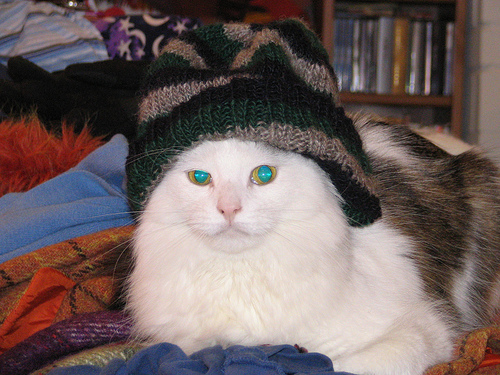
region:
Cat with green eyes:
[10, 3, 485, 360]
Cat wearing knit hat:
[117, 18, 492, 361]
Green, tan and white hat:
[117, 15, 382, 225]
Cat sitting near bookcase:
[100, 4, 481, 361]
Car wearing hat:
[124, 18, 462, 336]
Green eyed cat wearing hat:
[121, 19, 482, 349]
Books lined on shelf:
[321, 3, 486, 107]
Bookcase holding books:
[319, 3, 469, 103]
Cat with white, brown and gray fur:
[111, 39, 494, 336]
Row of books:
[322, 11, 461, 101]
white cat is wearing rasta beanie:
[109, 67, 475, 363]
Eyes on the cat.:
[160, 125, 379, 222]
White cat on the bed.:
[111, 112, 431, 364]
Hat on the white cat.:
[112, 28, 374, 217]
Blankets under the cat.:
[50, 95, 258, 350]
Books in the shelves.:
[324, 8, 469, 117]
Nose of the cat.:
[172, 181, 299, 268]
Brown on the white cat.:
[360, 137, 495, 297]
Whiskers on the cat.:
[132, 200, 460, 302]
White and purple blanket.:
[79, 16, 209, 76]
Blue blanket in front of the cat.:
[75, 337, 301, 372]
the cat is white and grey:
[172, 153, 491, 367]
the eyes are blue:
[173, 158, 305, 210]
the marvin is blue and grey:
[150, 21, 379, 188]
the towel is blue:
[11, 174, 124, 251]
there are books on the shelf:
[330, 12, 462, 96]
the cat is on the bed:
[143, 72, 495, 314]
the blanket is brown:
[6, 246, 118, 310]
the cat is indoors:
[3, 18, 498, 368]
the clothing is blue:
[102, 348, 282, 374]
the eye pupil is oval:
[162, 138, 338, 260]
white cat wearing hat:
[104, 14, 486, 369]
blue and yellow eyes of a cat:
[169, 161, 299, 194]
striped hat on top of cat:
[116, 11, 369, 166]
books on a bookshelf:
[339, 8, 458, 107]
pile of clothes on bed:
[0, 156, 137, 343]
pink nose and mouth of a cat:
[204, 192, 251, 239]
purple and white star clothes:
[96, 9, 200, 64]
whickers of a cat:
[86, 204, 202, 260]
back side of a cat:
[371, 123, 498, 341]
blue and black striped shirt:
[0, 0, 107, 70]